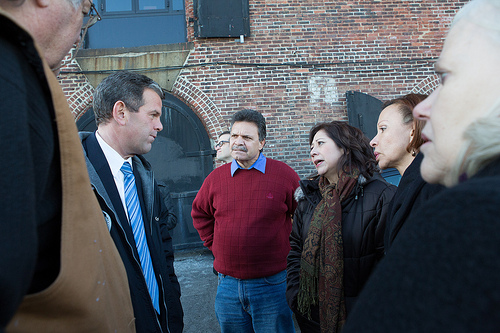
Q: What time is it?
A: Afternoon.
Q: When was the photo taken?
A: During the daytime.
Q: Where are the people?
A: Outside somewhere.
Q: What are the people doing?
A: Talking.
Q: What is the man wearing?
A: Red.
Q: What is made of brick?
A: The building.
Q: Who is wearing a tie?
A: A man.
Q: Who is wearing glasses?
A: One of the men.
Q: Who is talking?
A: Woman wearing a scarf.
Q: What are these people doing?
A: Talking.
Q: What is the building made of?
A: Brick.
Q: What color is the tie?
A: Blue.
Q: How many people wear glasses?
A: Two.